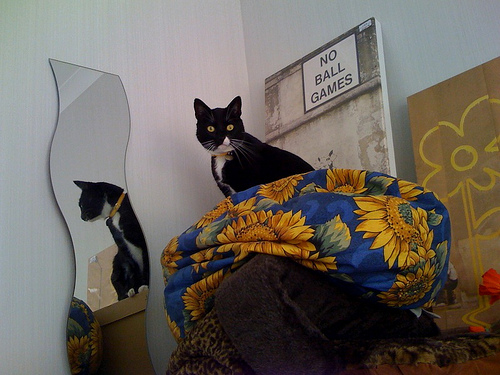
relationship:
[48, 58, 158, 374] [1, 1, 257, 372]
mirror against wall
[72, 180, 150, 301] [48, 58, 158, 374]
reflection of cat in mirror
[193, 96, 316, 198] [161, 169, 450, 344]
cat on blanket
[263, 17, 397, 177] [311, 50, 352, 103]
board has writing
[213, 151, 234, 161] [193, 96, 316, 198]
collar on cat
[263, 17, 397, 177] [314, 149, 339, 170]
board with drawing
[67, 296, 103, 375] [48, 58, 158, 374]
blanket's reflection in mirror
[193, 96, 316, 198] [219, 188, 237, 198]
cat has leg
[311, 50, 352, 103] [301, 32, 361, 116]
writing on sign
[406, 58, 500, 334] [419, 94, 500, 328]
cardboard has flower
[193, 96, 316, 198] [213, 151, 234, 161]
cat has collar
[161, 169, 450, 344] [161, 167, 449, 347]
blanket has sunflowers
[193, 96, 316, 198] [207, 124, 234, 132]
cat has eyes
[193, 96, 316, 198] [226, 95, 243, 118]
cat has ear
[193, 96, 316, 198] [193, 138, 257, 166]
cat has whiskers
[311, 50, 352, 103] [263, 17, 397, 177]
writing on board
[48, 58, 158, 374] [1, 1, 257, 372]
mirror on wall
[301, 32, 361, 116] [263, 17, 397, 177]
sign on board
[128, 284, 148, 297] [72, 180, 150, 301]
paws on reflection of cat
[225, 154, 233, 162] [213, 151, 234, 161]
identification tag on collar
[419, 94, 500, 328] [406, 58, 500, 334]
flower on cardboard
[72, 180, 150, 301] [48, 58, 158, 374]
reflection of cat in a mirror